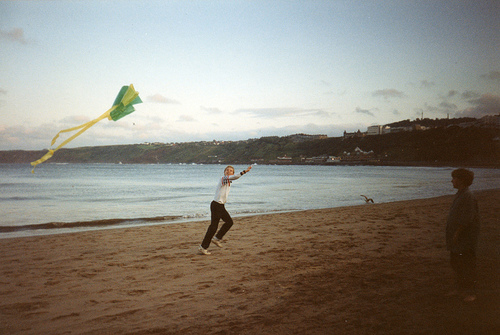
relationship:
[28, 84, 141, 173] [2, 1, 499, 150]
kite in sky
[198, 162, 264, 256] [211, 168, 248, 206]
man wearing a shirt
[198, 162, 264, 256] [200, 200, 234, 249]
man wearing pants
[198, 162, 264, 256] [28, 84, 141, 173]
man flying a kite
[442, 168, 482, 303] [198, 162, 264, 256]
boy watching man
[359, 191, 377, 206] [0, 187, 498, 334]
bird on sand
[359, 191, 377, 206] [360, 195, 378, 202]
bird has wings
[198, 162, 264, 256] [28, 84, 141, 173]
man looking at kite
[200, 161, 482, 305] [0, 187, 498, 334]
people are on sand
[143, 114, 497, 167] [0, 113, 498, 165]
houses are on hill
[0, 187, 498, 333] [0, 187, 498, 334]
beach has sand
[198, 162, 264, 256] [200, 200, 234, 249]
man has pants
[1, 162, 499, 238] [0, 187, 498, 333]
water near beach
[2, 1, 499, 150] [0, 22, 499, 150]
sky has clouds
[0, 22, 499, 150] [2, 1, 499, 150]
clouds are in sky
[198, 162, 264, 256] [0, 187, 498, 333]
man running on beach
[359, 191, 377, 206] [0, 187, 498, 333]
bird landing on beach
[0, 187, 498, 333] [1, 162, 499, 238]
beach near water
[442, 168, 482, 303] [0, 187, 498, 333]
boy standing on beach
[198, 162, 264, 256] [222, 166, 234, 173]
man has blonde hair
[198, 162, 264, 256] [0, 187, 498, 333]
man on beach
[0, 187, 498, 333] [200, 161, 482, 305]
beach below people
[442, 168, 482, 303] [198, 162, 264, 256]
boy to right of man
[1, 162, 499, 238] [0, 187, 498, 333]
water to left of beach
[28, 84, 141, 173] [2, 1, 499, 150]
kite flying in sky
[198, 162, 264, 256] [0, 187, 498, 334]
man running on sand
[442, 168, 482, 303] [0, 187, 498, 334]
boy standing on sand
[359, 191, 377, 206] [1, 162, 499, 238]
bird next to water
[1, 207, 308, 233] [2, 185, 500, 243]
wave close to shore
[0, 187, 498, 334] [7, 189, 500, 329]
sand has footprints